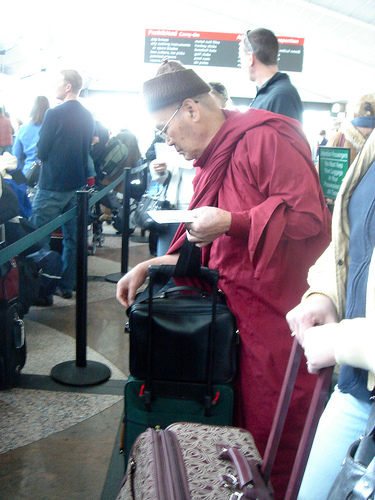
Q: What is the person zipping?
A: A suitcase.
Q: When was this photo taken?
A: During the daytime.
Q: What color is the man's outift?
A: Red.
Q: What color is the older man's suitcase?
A: Black.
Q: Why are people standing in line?
A: Waiting to check in.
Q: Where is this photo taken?
A: At an airport.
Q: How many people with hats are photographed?
A: One.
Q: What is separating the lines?
A: Black Ribbons.